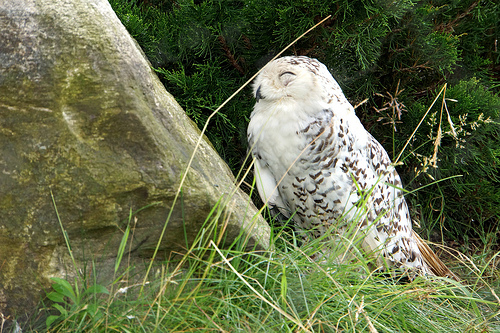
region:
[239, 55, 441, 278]
White and brown owl in front of rock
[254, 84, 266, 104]
Black nose on white and brown owl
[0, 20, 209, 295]
Green marking on rock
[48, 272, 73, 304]
Small green leaf next to rock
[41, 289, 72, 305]
Small green leaf next to rock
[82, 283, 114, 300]
Small green leaf next to rock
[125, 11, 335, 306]
Long strand of grass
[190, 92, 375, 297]
Long strand of grass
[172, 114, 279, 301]
Long strand of grass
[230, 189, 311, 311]
Long strand of grass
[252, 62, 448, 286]
white owl in grass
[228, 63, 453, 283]
own with eyes closed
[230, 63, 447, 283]
owl is white and black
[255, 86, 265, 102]
black beak of owl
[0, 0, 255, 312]
rock beside owl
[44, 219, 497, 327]
green grass by owl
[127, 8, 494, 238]
bush behind owl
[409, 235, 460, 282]
brown tail of owl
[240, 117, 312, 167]
white chest of owl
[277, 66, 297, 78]
closed eye of owl that is white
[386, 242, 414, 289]
part of the grass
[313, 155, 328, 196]
part of a feather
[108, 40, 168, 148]
edge of a rock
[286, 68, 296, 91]
head of a bird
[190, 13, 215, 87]
part of the bush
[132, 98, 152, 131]
side of a rock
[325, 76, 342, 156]
back of a bird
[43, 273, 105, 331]
cluster of green drooping leaves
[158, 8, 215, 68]
green piney shrub needles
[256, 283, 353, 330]
brown and green grass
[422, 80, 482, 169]
drooping flowered weed with green background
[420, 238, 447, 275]
brown feathers with white stripe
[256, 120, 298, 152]
snowy white fluffy feathers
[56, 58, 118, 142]
fingerprint image on a rock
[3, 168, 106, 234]
yellow discoloration on rock with green grass blade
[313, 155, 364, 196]
snow white and brown feathers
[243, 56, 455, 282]
fluffy snow white and brown owl sitting in grassy area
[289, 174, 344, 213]
black and white feathers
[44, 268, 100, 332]
plant next to boulder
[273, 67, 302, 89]
closed owl eye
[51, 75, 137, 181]
green moss growing on boulder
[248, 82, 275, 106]
black beak of owl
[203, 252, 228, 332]
green grass in front of boulder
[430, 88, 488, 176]
sprig of dried yellow grass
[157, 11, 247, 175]
green pine tree next to boulder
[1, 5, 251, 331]
grey boulder with green moss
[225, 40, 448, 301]
white owl with black tipped wings